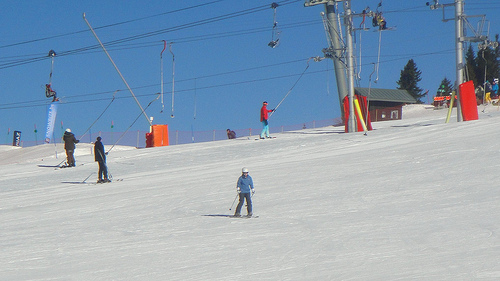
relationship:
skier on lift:
[356, 1, 399, 50] [367, 6, 397, 37]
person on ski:
[199, 154, 273, 252] [226, 207, 265, 227]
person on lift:
[199, 154, 273, 252] [367, 6, 397, 37]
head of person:
[242, 168, 248, 177] [199, 154, 273, 252]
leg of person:
[227, 199, 246, 228] [199, 154, 273, 252]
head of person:
[236, 166, 254, 185] [199, 154, 273, 252]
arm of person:
[233, 181, 242, 198] [199, 154, 273, 252]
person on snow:
[199, 154, 273, 252] [199, 219, 277, 257]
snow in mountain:
[199, 219, 277, 257] [349, 155, 436, 246]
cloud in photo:
[187, 37, 234, 80] [22, 22, 460, 281]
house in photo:
[344, 89, 411, 126] [22, 22, 460, 281]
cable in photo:
[3, 16, 129, 80] [22, 22, 460, 281]